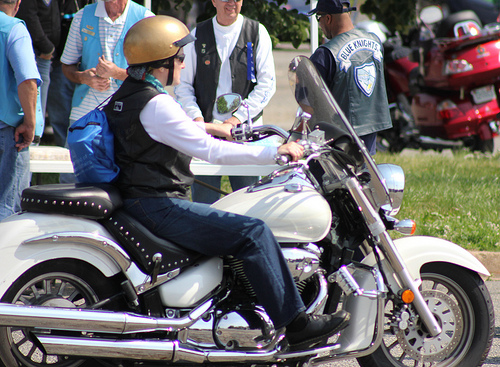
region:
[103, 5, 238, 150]
cyclist with gold helmet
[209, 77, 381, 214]
handle bars of motorcycle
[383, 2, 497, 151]
red motorcycle in back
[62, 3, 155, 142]
person with light blue vest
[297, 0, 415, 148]
man with emblem on back of jacket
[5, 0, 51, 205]
person with hand on right hip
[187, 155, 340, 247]
white gas tank of motorcycle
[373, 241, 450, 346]
orange reflector on wheel of motorcyll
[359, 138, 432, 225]
headlight of motorcylce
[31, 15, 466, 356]
A person is wearing dark sunglasses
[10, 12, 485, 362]
A person is wearing long pants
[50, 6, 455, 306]
A person is wearing a dark vest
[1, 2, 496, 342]
Some people are gathered together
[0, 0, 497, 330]
Some people are part of a club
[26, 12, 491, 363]
Some people are out in the sunshine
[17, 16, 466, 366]
Some people are enjoying the day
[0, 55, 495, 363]
black and white motorcycle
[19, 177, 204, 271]
black seat o white motorcycle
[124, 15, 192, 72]
black and golden helmet of motorcyclist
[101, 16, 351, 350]
man riding a big white motorcycle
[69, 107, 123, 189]
motocyclist have a blue bag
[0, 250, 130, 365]
black back wheel of motorcycle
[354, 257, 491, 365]
black front wheel of motorcycle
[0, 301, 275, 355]
large gray metal exhaust pipe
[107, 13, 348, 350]
motorcyclist wearing blue jeans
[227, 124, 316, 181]
gray metal chrome handle bar of motorcycle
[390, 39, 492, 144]
a red motorcycle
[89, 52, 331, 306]
a person sitting on a motorcycle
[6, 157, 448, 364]
a white motorcycle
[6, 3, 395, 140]
people standing next to the motorcycle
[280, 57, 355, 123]
the windshield on the motorcycle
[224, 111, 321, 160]
the handle bars on the motorcycle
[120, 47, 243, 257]
a person wearing a brown helmet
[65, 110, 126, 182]
a blue backpack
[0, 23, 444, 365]
a person riding a motorcycle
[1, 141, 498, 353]
a white and black motorcycle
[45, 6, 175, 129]
a blue vest over white shirt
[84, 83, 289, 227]
a black vest and white shirt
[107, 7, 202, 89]
a gold and black helmet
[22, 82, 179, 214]
a blue backpack with white letters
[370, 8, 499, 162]
a red and black motorcycle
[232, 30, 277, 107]
a blue ribbon on a vest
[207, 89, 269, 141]
a side mirror on bike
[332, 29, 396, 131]
name of biker gang on back